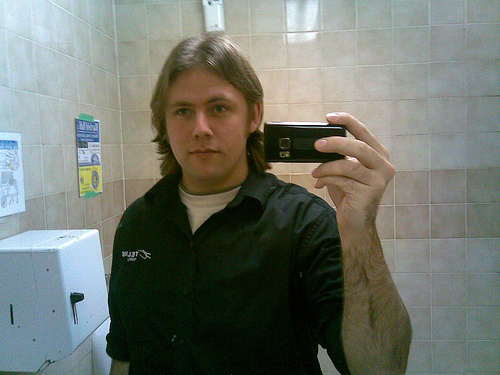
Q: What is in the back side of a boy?
A: Box.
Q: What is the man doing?
A: Taking selfie.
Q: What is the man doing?
A: Taking selfie.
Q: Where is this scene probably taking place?
A: Restroom.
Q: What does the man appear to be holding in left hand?
A: Cell phone.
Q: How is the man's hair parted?
A: In the middle.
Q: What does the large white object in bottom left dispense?
A: Paper towels.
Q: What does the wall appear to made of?
A: Ceramic tile.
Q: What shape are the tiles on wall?
A: Square.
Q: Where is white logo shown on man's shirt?
A: Right front side.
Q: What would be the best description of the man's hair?
A: Dark blond.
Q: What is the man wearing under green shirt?
A: White shirt.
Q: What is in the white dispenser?
A: Paper towels.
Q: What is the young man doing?
A: Taking a selfie.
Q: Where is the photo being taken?
A: In the bathroom.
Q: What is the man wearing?
A: Black shirt.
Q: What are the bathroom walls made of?
A: Square tiles.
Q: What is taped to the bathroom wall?
A: Papersl.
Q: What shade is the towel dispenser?
A: White;.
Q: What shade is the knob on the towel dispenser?
A: Black.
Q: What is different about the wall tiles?
A: Two different colors.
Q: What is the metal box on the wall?
A: A paper towel dispenser.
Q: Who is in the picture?
A: A young man.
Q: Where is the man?
A: In front of a bathroom mirror.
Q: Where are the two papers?
A: On the wall.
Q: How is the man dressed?
A: He is wearing a black buttoned down shirt.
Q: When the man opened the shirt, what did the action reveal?
A: A white t-shirt.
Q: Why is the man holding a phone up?
A: The man intends to take a selfie.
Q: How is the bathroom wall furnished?
A: It is covered with tiles.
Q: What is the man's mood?
A: He seems somber, as he is not smiling.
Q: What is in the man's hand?
A: A cell phone.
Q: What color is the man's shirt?
A: Black.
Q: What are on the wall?
A: Tiles.